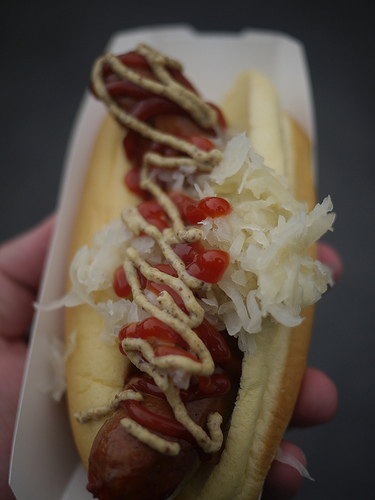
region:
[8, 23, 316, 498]
the paper bowl under the hot dog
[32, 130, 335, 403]
the sauerkraut on the hot dog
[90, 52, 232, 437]
the ketchup on the hot dog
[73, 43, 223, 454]
the mustard on the hot dog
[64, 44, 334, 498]
the loaded hot dog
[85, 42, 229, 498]
the hot dog on the bun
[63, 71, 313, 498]
the bun under the hot dog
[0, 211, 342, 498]
the hand holding the hot dog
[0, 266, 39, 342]
the lines in the bending thumb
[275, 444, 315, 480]
the piece of sauerkraut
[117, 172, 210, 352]
ketchup on hot dog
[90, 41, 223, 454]
sauerkraut on hot dog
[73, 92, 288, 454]
hot dog in white bun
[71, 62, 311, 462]
hot dog in paper basket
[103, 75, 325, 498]
hot dog in left hand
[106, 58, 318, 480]
condiments on hot dog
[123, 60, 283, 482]
hot dog is grilled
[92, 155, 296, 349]
cooked sauerkraut on hot dog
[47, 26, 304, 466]
a hotdog with condiments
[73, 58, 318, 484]
a hotdog bun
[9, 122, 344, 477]
a hand holding a hotdog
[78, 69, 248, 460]
mustard on a hotdog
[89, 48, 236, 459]
ketchup on a hotdog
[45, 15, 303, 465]
a white cardboard food container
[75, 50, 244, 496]
a cooked hotdog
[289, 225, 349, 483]
tips of fingers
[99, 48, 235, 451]
condiments squeezed on a hotdog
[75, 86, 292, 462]
a hot dog on a bun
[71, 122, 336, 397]
onions on a hot dog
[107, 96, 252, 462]
mustard on a hot dog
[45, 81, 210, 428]
a hot dog bun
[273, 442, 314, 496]
the pinky finger on a hand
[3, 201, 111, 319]
the thumb on a hand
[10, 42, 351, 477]
a hot dog in a paper holder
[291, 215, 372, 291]
the index finger on a hand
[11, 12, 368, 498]
a hot dog with the works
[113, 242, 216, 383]
a yelow spicy mustard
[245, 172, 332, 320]
some shredded saurkraut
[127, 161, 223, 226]
a line of red ketchup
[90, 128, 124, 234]
a fluffy hotdog bun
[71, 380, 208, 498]
a baked hotdog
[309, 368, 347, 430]
someones finger tip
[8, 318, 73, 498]
the box for the hotdog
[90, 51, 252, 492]
a line of red and white condiments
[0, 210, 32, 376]
a human palm holding a hotdog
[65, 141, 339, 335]
sauerkraut on a hotdog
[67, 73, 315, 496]
A fresh hotdog bun with fillings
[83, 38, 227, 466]
Dijon mustard on a hot dog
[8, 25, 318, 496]
a white paper hot dog holder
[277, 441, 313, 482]
sauerkraut on a finger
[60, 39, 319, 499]
A hot dog loaded with the works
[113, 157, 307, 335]
Toppings on a hot dog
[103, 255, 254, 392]
Toppings on a hot dog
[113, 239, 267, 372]
Toppings on a hot dog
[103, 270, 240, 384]
Toppings on a hot dog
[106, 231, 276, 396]
Toppings on a hot dog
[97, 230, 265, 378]
Toppings on a hot dog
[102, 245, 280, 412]
Toppings on a hot dog